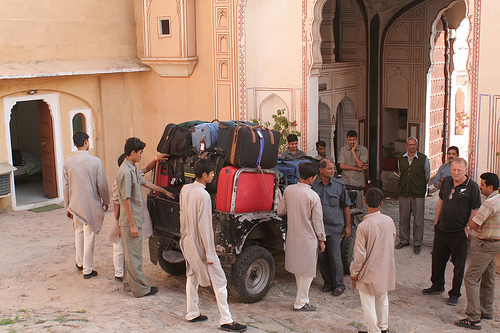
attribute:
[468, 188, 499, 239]
shirt — beige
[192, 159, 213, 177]
hair — black 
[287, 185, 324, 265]
shirt — beige 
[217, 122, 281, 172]
suitcase — black 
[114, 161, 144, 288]
coveralls — olive green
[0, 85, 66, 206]
door — open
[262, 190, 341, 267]
shirt — tan 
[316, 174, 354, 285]
uniform — blue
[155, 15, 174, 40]
window — small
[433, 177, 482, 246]
shirt — black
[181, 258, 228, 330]
pants — white